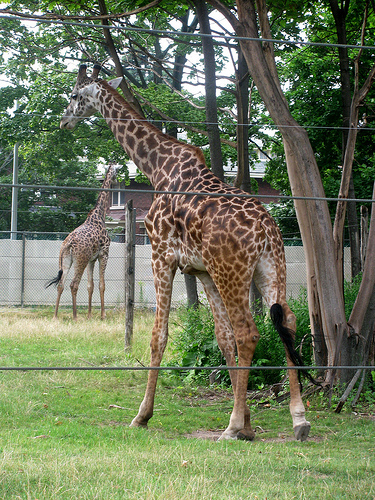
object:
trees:
[0, 2, 367, 331]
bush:
[158, 295, 318, 398]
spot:
[224, 279, 228, 286]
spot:
[235, 279, 243, 287]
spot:
[228, 283, 232, 289]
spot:
[221, 276, 228, 285]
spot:
[233, 275, 240, 283]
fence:
[0, 17, 374, 369]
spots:
[156, 143, 172, 155]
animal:
[59, 62, 325, 442]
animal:
[43, 163, 123, 320]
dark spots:
[161, 218, 171, 240]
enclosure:
[0, 0, 375, 374]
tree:
[194, 5, 375, 404]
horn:
[91, 62, 101, 79]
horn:
[77, 63, 87, 80]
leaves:
[294, 55, 338, 97]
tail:
[262, 213, 325, 390]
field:
[0, 292, 375, 500]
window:
[109, 189, 125, 210]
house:
[23, 157, 286, 246]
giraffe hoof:
[292, 424, 311, 440]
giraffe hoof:
[216, 435, 237, 443]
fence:
[0, 230, 303, 307]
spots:
[159, 310, 165, 318]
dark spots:
[152, 252, 159, 261]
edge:
[213, 1, 347, 387]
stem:
[204, 0, 373, 382]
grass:
[0, 296, 374, 500]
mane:
[98, 79, 205, 162]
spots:
[196, 216, 212, 233]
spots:
[173, 219, 187, 235]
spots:
[237, 250, 250, 266]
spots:
[173, 146, 182, 157]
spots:
[136, 140, 148, 159]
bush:
[339, 270, 362, 320]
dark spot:
[209, 230, 226, 247]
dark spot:
[217, 203, 230, 217]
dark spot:
[198, 163, 206, 171]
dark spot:
[157, 143, 172, 156]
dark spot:
[203, 173, 213, 179]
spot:
[220, 233, 227, 245]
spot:
[172, 207, 189, 218]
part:
[172, 421, 221, 466]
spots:
[204, 186, 220, 192]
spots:
[100, 206, 104, 211]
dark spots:
[183, 189, 196, 204]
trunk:
[283, 137, 372, 389]